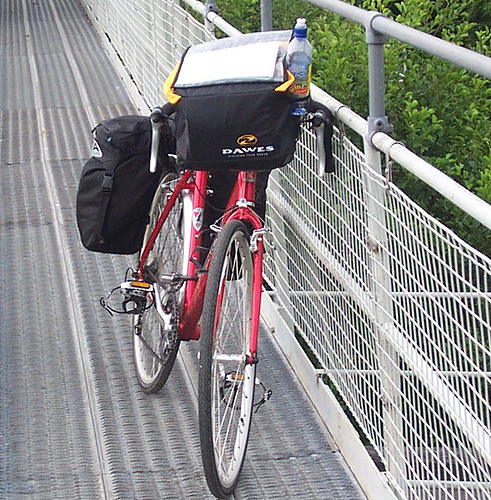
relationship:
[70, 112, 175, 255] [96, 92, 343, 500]
bag on bicycle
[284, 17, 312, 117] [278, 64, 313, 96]
bottle on holder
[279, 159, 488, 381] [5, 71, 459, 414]
wire screen on bridge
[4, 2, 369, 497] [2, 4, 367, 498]
metal on roadway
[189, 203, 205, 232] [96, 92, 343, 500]
logo on bicycle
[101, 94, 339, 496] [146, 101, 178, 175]
bicycle has bars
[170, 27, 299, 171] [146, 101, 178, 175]
bag on bars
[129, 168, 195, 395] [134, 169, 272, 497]
back tire of bicycle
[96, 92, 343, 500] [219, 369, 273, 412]
bicycle has pedal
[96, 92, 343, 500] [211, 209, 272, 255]
bicycle has front brakes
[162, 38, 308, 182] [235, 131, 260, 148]
bag with insignia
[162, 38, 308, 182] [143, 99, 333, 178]
bag on bars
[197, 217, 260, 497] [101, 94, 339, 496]
black tire on bicycle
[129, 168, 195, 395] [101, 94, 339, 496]
back tire on bicycle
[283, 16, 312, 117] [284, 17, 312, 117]
bottle full of bottle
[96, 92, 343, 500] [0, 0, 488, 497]
bicycle on bridge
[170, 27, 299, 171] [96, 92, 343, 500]
bag on front of bicycle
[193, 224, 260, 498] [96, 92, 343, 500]
black tire of bicycle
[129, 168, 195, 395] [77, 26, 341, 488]
back tire of bike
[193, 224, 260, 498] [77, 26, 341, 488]
black tire of bike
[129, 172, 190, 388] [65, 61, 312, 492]
back tire of bike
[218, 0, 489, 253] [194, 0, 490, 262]
leaves on bush